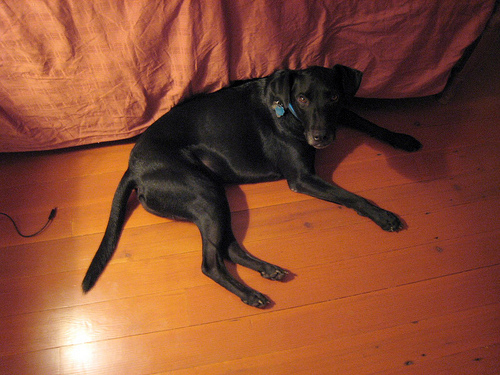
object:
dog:
[80, 63, 423, 309]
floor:
[331, 253, 403, 311]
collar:
[270, 99, 299, 118]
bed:
[0, 0, 499, 153]